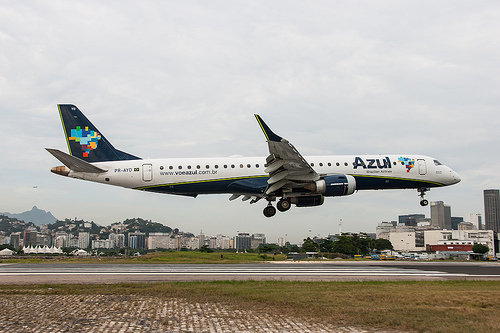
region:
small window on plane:
[158, 163, 165, 170]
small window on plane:
[167, 163, 172, 169]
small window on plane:
[176, 163, 182, 170]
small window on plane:
[194, 161, 202, 170]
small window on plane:
[212, 160, 219, 170]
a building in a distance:
[128, 231, 152, 249]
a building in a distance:
[148, 235, 182, 249]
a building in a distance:
[234, 234, 256, 256]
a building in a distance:
[253, 234, 270, 254]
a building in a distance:
[206, 235, 224, 263]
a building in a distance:
[198, 231, 213, 257]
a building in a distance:
[386, 233, 411, 255]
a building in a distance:
[464, 226, 497, 258]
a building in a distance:
[432, 195, 442, 227]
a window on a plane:
[168, 163, 177, 179]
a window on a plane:
[187, 159, 196, 174]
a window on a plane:
[204, 159, 215, 178]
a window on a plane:
[223, 160, 232, 175]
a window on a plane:
[228, 161, 245, 181]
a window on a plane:
[255, 161, 267, 171]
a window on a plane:
[310, 155, 327, 182]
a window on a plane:
[326, 158, 342, 173]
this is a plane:
[41, 97, 468, 289]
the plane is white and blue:
[12, 75, 477, 283]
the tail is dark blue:
[37, 95, 164, 186]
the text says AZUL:
[331, 148, 418, 210]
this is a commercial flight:
[81, 85, 371, 206]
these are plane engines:
[295, 165, 395, 220]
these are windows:
[142, 153, 332, 180]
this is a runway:
[108, 214, 462, 331]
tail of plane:
[53, 100, 136, 156]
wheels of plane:
[261, 188, 431, 220]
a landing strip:
[1, 263, 499, 274]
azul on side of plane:
[353, 152, 392, 169]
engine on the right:
[316, 173, 358, 195]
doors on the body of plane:
[141, 157, 430, 181]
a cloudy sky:
[2, 3, 496, 239]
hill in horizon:
[7, 202, 59, 222]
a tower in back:
[334, 215, 344, 237]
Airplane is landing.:
[44, 103, 461, 219]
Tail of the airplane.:
[57, 103, 142, 161]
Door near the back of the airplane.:
[141, 163, 152, 180]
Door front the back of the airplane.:
[418, 158, 425, 174]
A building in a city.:
[236, 230, 253, 251]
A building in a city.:
[148, 232, 174, 252]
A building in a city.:
[125, 230, 146, 252]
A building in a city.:
[111, 230, 126, 249]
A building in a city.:
[76, 231, 90, 251]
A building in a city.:
[426, 199, 446, 228]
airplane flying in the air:
[38, 87, 480, 224]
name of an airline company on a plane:
[345, 153, 417, 174]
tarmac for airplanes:
[2, 243, 484, 285]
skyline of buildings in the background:
[364, 176, 498, 250]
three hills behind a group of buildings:
[3, 210, 188, 250]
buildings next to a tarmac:
[383, 223, 498, 283]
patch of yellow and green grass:
[322, 293, 487, 322]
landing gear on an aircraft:
[227, 180, 328, 218]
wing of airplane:
[228, 100, 343, 213]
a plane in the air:
[34, 77, 465, 232]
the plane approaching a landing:
[14, 68, 499, 301]